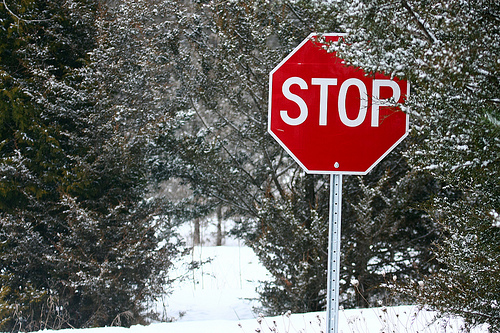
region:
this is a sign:
[237, 17, 412, 312]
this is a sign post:
[301, 140, 351, 330]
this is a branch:
[165, 60, 261, 237]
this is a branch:
[210, 25, 260, 107]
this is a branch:
[408, 200, 491, 302]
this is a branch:
[28, 180, 159, 318]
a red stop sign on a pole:
[266, 37, 423, 195]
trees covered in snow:
[116, 38, 278, 191]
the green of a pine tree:
[13, 40, 83, 178]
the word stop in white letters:
[287, 55, 396, 155]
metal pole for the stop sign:
[325, 159, 351, 331]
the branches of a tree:
[266, 158, 304, 196]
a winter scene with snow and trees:
[2, 1, 494, 329]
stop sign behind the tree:
[240, 23, 421, 182]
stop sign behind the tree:
[255, 41, 422, 178]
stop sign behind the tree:
[242, 17, 417, 177]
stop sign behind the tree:
[267, 20, 414, 175]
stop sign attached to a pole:
[318, 160, 347, 332]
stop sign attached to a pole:
[258, 19, 421, 325]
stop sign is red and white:
[267, 34, 411, 175]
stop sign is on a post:
[267, 33, 409, 175]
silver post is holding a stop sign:
[328, 175, 344, 331]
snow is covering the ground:
[2, 217, 494, 330]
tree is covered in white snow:
[49, 9, 319, 311]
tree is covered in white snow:
[1, 2, 191, 331]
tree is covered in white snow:
[318, 4, 498, 331]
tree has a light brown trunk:
[189, 194, 201, 244]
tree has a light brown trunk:
[216, 202, 223, 244]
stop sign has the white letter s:
[281, 76, 308, 124]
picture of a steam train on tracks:
[272, 203, 285, 226]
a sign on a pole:
[284, 28, 451, 300]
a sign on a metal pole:
[269, 4, 397, 284]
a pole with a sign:
[289, 13, 365, 285]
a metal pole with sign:
[269, 47, 395, 323]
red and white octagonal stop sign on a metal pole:
[262, 30, 410, 331]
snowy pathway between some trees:
[148, 205, 286, 323]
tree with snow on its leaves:
[309, 0, 498, 331]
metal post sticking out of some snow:
[319, 170, 343, 332]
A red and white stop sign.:
[266, 25, 416, 183]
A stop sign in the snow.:
[257, 27, 417, 330]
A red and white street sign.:
[269, 26, 410, 179]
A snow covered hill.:
[149, 230, 288, 332]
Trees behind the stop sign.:
[16, 9, 497, 331]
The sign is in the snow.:
[266, 27, 421, 332]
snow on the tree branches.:
[132, 9, 498, 311]